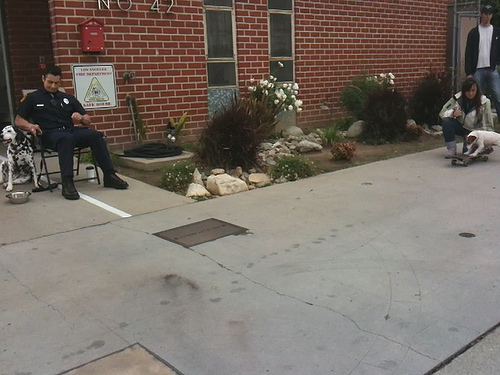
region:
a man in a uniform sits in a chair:
[12, 57, 129, 203]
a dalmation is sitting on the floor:
[0, 120, 44, 192]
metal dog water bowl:
[4, 186, 34, 206]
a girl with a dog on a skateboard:
[436, 78, 498, 172]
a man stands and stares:
[461, 3, 498, 112]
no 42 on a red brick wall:
[96, 0, 181, 17]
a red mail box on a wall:
[76, 11, 111, 56]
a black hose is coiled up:
[123, 134, 186, 161]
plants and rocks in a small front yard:
[116, 54, 446, 203]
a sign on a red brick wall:
[72, 61, 121, 112]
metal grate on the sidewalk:
[151, 205, 255, 252]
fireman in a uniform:
[13, 48, 128, 215]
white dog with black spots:
[0, 117, 49, 214]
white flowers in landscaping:
[243, 49, 321, 145]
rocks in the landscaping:
[180, 162, 276, 195]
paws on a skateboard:
[443, 147, 486, 174]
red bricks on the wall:
[316, 12, 353, 51]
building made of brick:
[52, 2, 459, 133]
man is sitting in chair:
[13, 65, 130, 201]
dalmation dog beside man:
[1, 57, 130, 211]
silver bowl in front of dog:
[1, 122, 43, 205]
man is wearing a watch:
[77, 113, 89, 124]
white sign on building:
[71, 60, 119, 112]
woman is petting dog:
[437, 72, 499, 169]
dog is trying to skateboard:
[440, 128, 499, 165]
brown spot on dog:
[462, 129, 478, 146]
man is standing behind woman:
[435, 1, 496, 170]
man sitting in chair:
[0, 62, 117, 172]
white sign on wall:
[70, 53, 122, 117]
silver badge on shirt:
[59, 99, 69, 111]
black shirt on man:
[14, 90, 91, 130]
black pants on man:
[36, 112, 110, 186]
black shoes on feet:
[60, 175, 130, 216]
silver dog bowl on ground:
[6, 189, 33, 205]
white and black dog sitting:
[0, 118, 36, 181]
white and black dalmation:
[0, 120, 34, 181]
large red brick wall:
[265, 7, 431, 126]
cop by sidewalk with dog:
[1, 23, 214, 353]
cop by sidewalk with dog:
[0, 18, 135, 143]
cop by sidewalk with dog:
[8, 30, 114, 238]